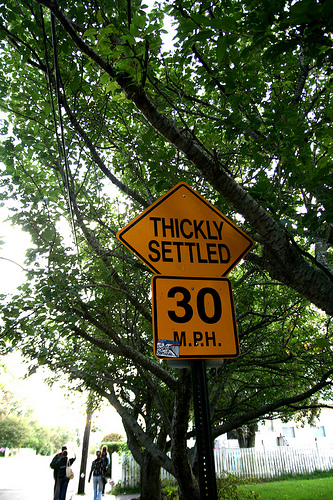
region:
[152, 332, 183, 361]
Sticker placed on the traffic sign.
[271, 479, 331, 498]
Green grass growing on the ground.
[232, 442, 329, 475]
White fence lining the yard.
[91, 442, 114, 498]
People walking in the sidewalk.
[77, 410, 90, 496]
Tall brown light pole on the sidewalk.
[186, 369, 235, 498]
Metal street post with holes in it.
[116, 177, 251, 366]
Orange and black road signs.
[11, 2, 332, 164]
Beautiful green leaves growing on the trees.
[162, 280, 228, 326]
Number 30 in large black print.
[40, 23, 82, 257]
Black power line traveling through the trees.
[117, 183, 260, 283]
a diamond shaped yellow sign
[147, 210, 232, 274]
the words Thickly Settled on a sign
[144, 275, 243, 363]
a 30 mph street sign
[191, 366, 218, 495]
a metal street sign pole with holes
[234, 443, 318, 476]
a white wooden picket fence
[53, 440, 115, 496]
a group of people on a sidewalk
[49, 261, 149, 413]
two green trees behind the street sign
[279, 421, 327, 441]
two windows on the side of a house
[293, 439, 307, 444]
white paneling on the side of a house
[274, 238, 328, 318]
a big thick gray tree branch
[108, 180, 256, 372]
The sign is yellow.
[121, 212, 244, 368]
The sign has black lettering on it.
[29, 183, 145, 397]
The tree is leafy.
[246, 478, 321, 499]
The grass is lush.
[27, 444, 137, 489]
The people are standing.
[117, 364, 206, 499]
The trunks are brown.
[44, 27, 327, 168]
The trees have several leaves on them.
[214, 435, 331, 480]
The fence is white.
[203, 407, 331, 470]
The building is white.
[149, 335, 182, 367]
The sticker is white and blue.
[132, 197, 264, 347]
the community is thickly settled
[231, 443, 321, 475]
the fence is white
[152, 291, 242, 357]
speed allowed is 30mph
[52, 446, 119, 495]
the people are on the pavement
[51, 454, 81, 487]
she is carrying a hand bag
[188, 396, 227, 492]
the post is mettalic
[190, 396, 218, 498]
the post has holes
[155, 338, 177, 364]
a sticker is on the sign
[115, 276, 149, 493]
the shape is square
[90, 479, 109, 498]
she has blue jeans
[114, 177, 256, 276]
yellow diamond-shaped street sign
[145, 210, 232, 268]
"thickly settled" print on street sign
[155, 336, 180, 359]
sticker on speed limit sign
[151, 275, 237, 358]
30 M.P.H. speed limit sign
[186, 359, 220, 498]
black street sign pole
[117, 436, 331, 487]
white picket fence behind trees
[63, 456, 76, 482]
white tote bag on woman's arm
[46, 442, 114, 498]
people walking on side walk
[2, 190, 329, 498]
small leafy trees behind street sign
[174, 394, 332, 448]
white building behind picket fence